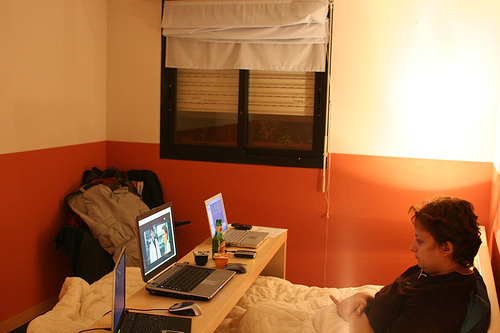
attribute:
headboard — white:
[468, 224, 496, 332]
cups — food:
[187, 249, 228, 268]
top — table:
[126, 222, 285, 315]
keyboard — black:
[160, 263, 212, 293]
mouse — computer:
[169, 301, 200, 316]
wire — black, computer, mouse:
[126, 307, 166, 314]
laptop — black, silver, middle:
[138, 201, 235, 301]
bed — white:
[219, 277, 378, 332]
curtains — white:
[159, 0, 329, 76]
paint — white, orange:
[334, 14, 492, 247]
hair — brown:
[411, 197, 481, 267]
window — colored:
[159, 1, 330, 167]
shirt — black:
[363, 263, 487, 330]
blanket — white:
[217, 272, 381, 327]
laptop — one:
[110, 246, 192, 330]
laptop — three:
[202, 192, 267, 252]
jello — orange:
[214, 250, 230, 265]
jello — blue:
[192, 248, 209, 266]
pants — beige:
[67, 183, 151, 262]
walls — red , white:
[104, 19, 474, 303]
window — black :
[145, 14, 340, 194]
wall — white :
[123, 13, 415, 270]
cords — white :
[322, 23, 357, 218]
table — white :
[105, 159, 281, 331]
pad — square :
[187, 262, 243, 298]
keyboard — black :
[160, 248, 211, 295]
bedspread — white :
[44, 238, 359, 331]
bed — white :
[57, 240, 424, 330]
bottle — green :
[204, 202, 230, 263]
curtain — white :
[160, 20, 334, 97]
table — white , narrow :
[65, 187, 321, 330]